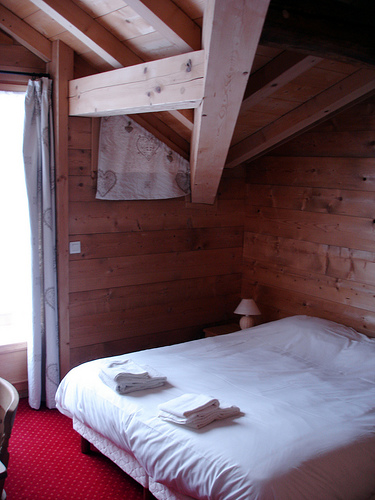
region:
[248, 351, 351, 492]
the bed is white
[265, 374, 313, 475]
the bed is white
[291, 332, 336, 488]
the bed is white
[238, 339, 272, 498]
the bed is white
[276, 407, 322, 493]
the bed is white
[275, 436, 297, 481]
the bed is white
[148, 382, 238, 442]
white towels on bed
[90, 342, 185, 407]
stack of towels on bed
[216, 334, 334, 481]
big white sheets on bed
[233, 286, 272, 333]
small white lamp by bed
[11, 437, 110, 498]
red carpet in room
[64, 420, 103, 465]
wooden post for bed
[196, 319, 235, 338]
nightstand by bed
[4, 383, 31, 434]
top of some white chair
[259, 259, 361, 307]
wooden wall most likely oak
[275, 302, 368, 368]
head of white bed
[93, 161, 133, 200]
HEARTS ARE ON THE CURTAIN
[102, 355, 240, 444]
TOWELS ARE ON THE BED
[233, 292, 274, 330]
LAMP IS ON THE BEDSIDE TABLE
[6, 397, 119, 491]
RED CARPETING IS ON THE FLOOR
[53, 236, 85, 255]
A LIGHT SWITCH TO THE RIGHT OF THE DOOR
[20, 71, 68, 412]
CURTAINS ARE HANGING TO THE RIGHT OF WINDOW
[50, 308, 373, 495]
WHITE SHEETS ARE ON THE BED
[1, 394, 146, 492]
CARPET IS RED AND GOLD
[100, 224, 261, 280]
KNOTTY PINE IS ON THE WALL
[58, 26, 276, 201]
RAFTERS ARE EXPOSED WOOD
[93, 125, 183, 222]
piece of material on wall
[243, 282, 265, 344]
small yellow bed side lamp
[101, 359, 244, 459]
two piles of towels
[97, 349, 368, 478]
white bedspread on bed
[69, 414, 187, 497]
two box springs puled together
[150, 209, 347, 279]
wooden wall panel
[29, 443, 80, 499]
red polka dot rug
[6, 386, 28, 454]
wooden rounded chair near desk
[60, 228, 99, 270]
small white light switch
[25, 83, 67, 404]
light gray long curtain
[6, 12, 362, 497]
a room under a roof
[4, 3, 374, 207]
structure of a roof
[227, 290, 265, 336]
a lamp on side table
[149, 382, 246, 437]
white towels on a bed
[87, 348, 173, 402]
white towels on a white bed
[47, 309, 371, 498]
bed is covered with a sheet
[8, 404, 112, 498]
red carpet of room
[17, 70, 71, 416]
a white curtain in room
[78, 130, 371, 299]
wall of room is wood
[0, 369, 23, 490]
backseat of a chair